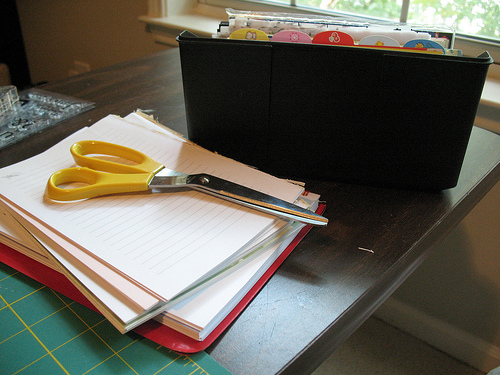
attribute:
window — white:
[149, 3, 497, 120]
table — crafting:
[248, 184, 383, 322]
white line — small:
[357, 246, 374, 254]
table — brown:
[1, 46, 498, 373]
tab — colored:
[309, 26, 351, 44]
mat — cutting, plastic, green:
[23, 299, 84, 373]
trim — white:
[372, 295, 498, 373]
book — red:
[3, 170, 328, 355]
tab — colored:
[355, 34, 399, 49]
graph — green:
[8, 253, 196, 374]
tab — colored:
[0, 96, 336, 353]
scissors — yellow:
[47, 138, 329, 233]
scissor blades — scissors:
[143, 166, 335, 228]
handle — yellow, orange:
[46, 139, 163, 201]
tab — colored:
[273, 27, 317, 47]